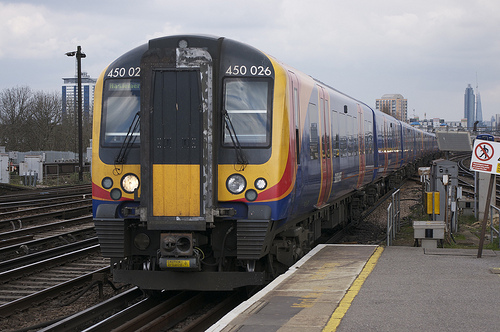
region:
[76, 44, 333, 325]
the train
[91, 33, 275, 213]
the train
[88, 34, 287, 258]
the front of a yellow train.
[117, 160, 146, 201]
a headlight on a train.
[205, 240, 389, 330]
a loading platform near a train.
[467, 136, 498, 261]
a no crossing sign.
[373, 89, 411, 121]
a tall multi story building.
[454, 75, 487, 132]
a very tall building.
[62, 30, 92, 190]
a light pole near a train.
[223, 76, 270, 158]
a window on the front of a train.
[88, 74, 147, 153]
a window on the right.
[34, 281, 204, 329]
a set of train tracks.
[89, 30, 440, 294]
blue, yellow and red train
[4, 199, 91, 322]
several train tracks in a row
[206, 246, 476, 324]
passenger train platform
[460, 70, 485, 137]
two tall skyscrapers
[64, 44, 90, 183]
tall black light pole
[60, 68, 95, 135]
blue and white apartment complex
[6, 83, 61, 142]
deciduous trees with no leaves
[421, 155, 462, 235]
silver electrical box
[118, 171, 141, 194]
headlight on front of train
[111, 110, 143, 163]
windshield wiper on front train window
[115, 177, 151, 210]
one light is on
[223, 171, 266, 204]
one light is out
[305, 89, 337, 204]
the doors are red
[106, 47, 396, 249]
transportation is the train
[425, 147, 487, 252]
electric box is gray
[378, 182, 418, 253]
the rails are silver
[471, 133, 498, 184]
the sign is white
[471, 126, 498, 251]
sign on the pole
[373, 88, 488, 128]
buildings in the distance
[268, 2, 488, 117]
the sky is cloudy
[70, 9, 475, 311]
a train on the tracks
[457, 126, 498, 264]
a white and red sign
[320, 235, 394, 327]
a yellow stripe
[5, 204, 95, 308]
train tracks on the ground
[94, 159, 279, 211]
headlights on the train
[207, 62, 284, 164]
windshield of the train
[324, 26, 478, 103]
dark stormy sky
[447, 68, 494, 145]
tall buildings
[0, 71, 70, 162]
bare brown trees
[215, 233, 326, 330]
white line on the curb